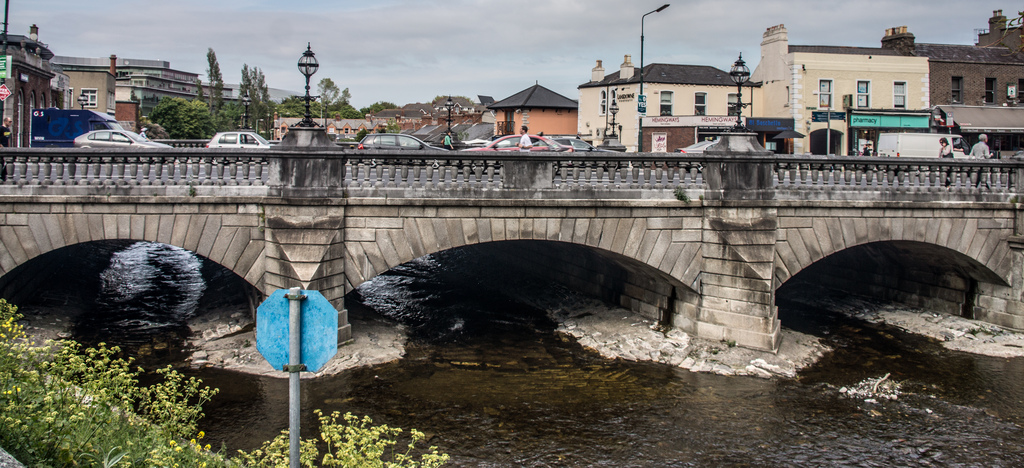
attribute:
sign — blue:
[251, 278, 355, 382]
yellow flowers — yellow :
[40, 335, 196, 454]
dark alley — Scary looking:
[313, 212, 726, 375]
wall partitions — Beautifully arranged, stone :
[406, 206, 581, 239]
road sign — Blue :
[252, 268, 346, 443]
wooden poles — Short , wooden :
[341, 145, 529, 202]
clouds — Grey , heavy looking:
[362, 18, 535, 68]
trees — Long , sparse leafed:
[189, 46, 313, 155]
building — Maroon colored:
[479, 80, 613, 141]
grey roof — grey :
[481, 78, 568, 122]